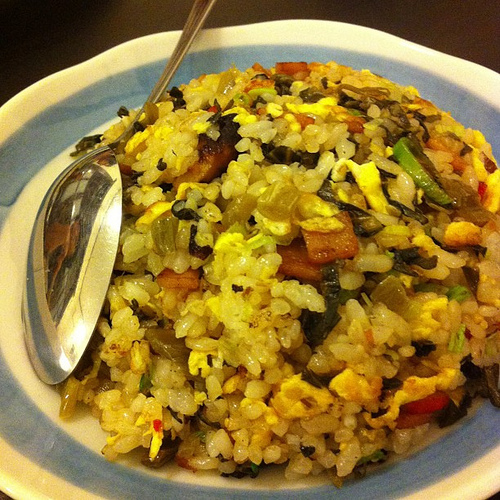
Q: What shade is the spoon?
A: Silver.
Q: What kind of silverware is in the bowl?
A: A spoon.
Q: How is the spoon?
A: Shiny.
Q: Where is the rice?
A: In bowl.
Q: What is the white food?
A: Rice.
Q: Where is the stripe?
A: On bowl.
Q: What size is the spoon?
A: Large.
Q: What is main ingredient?
A: Rice.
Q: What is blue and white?
A: Bowl.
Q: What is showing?
A: Some green.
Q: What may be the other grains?
A: Barley.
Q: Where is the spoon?
A: Laying in a dish of food.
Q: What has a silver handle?
A: Spoon.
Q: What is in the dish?
A: An egg and vegetable rice.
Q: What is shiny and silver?
A: Spoon.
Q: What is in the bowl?
A: Rice.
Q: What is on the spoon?
A: Person's reflection.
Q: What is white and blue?
A: Plate.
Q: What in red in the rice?
A: Tomato.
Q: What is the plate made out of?
A: Ceramic.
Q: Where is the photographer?
A: In spoon reflection.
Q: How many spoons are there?
A: One.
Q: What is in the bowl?
A: Rice.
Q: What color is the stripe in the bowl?
A: Blue.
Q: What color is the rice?
A: Yellow.